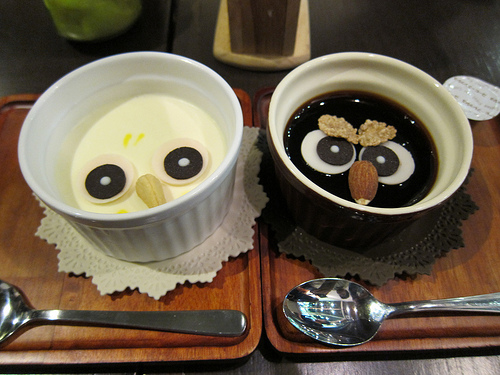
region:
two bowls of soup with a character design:
[35, 37, 478, 272]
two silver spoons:
[6, 265, 493, 354]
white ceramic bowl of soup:
[25, 46, 244, 255]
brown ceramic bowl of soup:
[257, 56, 469, 251]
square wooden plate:
[2, 73, 246, 366]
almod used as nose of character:
[350, 156, 380, 204]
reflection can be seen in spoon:
[297, 278, 383, 338]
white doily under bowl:
[62, 95, 267, 288]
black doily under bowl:
[257, 67, 477, 267]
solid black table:
[349, 18, 479, 45]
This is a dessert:
[112, 106, 410, 320]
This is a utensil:
[260, 265, 343, 367]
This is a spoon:
[263, 258, 453, 360]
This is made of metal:
[296, 261, 420, 343]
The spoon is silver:
[278, 273, 426, 365]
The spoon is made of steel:
[324, 269, 407, 334]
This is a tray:
[255, 279, 462, 366]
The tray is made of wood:
[234, 242, 288, 303]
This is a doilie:
[247, 205, 444, 325]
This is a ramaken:
[261, 200, 351, 272]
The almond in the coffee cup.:
[350, 152, 381, 205]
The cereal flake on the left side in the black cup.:
[316, 113, 359, 139]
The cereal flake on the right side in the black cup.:
[357, 112, 395, 145]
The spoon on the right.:
[278, 274, 496, 346]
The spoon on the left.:
[0, 275, 246, 350]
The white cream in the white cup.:
[50, 108, 216, 187]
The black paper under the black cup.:
[264, 142, 468, 286]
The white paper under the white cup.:
[22, 125, 289, 300]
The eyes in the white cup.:
[59, 147, 202, 193]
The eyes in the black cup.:
[306, 130, 421, 192]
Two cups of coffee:
[14, 49, 478, 269]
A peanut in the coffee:
[342, 153, 382, 208]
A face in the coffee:
[283, 86, 440, 209]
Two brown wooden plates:
[0, 86, 499, 366]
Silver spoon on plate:
[280, 271, 499, 352]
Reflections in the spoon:
[282, 276, 382, 346]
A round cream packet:
[439, 69, 499, 128]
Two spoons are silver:
[2, 276, 499, 349]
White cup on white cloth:
[18, 46, 271, 308]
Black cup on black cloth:
[256, 45, 480, 286]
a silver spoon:
[274, 269, 498, 357]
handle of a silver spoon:
[32, 296, 253, 351]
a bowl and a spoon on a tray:
[252, 46, 496, 373]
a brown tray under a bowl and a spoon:
[0, 53, 262, 371]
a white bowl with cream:
[15, 41, 255, 267]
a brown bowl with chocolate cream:
[245, 45, 482, 255]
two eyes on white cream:
[52, 88, 214, 219]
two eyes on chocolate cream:
[294, 116, 422, 196]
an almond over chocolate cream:
[342, 158, 382, 219]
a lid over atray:
[448, 66, 498, 171]